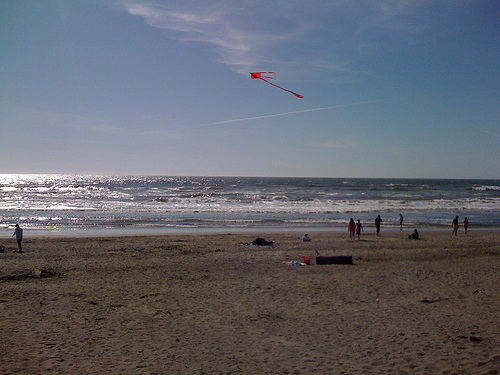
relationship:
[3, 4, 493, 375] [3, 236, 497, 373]
beach with sand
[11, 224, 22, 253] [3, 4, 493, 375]
person in beach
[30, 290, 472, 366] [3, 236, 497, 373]
foot prints in sand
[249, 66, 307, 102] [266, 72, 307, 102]
kite has tail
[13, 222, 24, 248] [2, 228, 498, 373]
person on beach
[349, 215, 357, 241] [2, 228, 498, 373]
person on beach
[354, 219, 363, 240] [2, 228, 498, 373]
person on beach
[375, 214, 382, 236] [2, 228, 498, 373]
person on beach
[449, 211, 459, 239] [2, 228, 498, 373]
person on beach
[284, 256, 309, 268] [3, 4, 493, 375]
someone on beach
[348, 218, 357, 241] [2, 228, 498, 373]
person on beach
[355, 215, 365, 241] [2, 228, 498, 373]
person on beach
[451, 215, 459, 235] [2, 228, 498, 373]
person on beach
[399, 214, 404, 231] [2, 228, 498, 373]
person on beach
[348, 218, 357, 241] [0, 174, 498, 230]
person on ocean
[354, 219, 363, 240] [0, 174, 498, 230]
person on ocean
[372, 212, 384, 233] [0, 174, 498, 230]
person on ocean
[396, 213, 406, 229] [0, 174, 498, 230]
person on ocean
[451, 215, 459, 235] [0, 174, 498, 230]
person on ocean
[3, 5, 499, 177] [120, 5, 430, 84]
sky has clouds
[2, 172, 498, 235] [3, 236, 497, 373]
ocean beside sand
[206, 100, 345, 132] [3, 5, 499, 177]
trail in sky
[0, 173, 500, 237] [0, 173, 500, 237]
ocean on ocean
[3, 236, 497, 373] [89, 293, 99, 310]
sand covered by footprint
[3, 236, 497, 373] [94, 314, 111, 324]
sand covered by footprint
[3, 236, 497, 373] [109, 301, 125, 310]
sand covered by footprint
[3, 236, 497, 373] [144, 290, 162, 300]
sand covered by footprint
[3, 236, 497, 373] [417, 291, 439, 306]
sand covered by footprint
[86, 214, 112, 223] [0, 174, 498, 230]
ripple in ocean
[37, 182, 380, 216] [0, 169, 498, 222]
ripple in ocean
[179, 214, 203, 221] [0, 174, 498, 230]
ripple in ocean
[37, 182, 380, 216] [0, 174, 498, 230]
ripple in ocean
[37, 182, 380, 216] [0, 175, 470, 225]
ripple in ocean